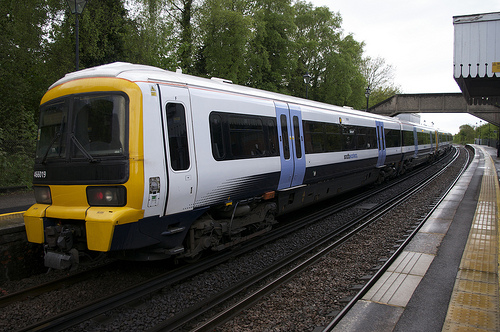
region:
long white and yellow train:
[21, 63, 452, 275]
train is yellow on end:
[21, 80, 144, 272]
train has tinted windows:
[33, 90, 455, 184]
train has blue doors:
[273, 99, 433, 193]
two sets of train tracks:
[2, 141, 472, 331]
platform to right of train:
[322, 144, 498, 330]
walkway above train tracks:
[355, 90, 499, 130]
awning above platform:
[444, 8, 498, 107]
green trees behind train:
[1, 0, 395, 186]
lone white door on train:
[151, 75, 206, 232]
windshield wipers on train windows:
[34, 126, 96, 168]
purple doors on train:
[265, 98, 317, 188]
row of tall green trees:
[29, 0, 332, 85]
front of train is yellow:
[17, 74, 152, 244]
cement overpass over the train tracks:
[361, 82, 495, 124]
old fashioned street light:
[52, 0, 99, 83]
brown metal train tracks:
[197, 224, 307, 330]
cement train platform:
[390, 155, 493, 316]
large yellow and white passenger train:
[24, 74, 461, 261]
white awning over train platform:
[449, 21, 499, 99]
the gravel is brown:
[323, 262, 358, 280]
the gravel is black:
[163, 284, 204, 301]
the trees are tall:
[225, 2, 371, 59]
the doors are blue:
[271, 94, 310, 193]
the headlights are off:
[26, 179, 128, 216]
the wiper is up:
[66, 112, 103, 169]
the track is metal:
[214, 278, 261, 313]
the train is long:
[15, 58, 462, 285]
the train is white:
[12, 52, 466, 262]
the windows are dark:
[303, 116, 374, 159]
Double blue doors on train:
[274, 103, 306, 195]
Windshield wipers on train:
[66, 134, 99, 166]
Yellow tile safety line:
[466, 221, 494, 324]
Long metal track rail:
[271, 241, 318, 283]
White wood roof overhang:
[453, 29, 487, 79]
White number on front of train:
[31, 169, 50, 180]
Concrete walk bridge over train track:
[393, 91, 455, 117]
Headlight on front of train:
[82, 183, 132, 208]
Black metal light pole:
[66, 1, 86, 68]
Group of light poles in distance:
[471, 116, 493, 146]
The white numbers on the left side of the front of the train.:
[25, 165, 50, 180]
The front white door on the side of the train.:
[157, 79, 203, 212]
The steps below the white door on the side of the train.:
[160, 212, 193, 259]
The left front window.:
[32, 111, 67, 166]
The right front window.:
[69, 92, 128, 161]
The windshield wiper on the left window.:
[30, 110, 72, 162]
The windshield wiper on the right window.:
[69, 120, 89, 165]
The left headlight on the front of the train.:
[19, 180, 61, 207]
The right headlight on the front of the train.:
[80, 185, 131, 205]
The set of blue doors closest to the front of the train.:
[272, 100, 314, 193]